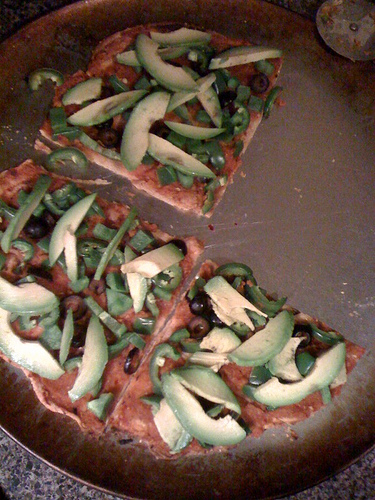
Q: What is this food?
A: Pizza.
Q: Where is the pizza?
A: On stone.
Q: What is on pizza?
A: Black olives.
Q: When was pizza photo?
A: After eating.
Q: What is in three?
A: Slices of pizza.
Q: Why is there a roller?
A: Cutting pizza.